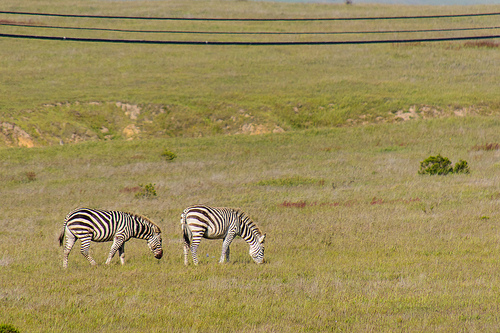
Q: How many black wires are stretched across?
A: 3.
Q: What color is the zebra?
A: Black and white.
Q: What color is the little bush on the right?
A: Green.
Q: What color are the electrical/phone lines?
A: Black.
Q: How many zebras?
A: 2.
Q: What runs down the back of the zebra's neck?
A: A mane.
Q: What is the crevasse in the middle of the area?
A: A ditch.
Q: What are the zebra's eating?
A: Grass.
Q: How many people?
A: None.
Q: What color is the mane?
A: Light brown.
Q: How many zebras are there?
A: Two.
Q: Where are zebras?
A: In field.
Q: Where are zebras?
A: In field.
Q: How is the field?
A: Grassy.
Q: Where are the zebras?
A: In field.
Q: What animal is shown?
A: Zebra.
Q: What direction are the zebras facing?
A: Right.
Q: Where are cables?
A: Above field.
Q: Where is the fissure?
A: In field.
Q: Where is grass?
A: In field.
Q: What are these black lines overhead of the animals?
A: Power lines.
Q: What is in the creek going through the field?
A: Water.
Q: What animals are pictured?
A: Zebra.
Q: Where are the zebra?
A: In a field.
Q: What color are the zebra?
A: White and black.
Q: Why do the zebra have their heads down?
A: They are eating.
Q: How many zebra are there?
A: Two.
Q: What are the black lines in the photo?
A: Power lines.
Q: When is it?
A: Day time.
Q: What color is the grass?
A: Green.